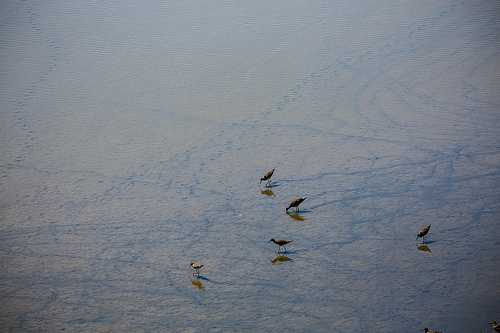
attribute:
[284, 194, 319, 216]
bird — walking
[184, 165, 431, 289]
birds flock — looking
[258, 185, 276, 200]
shadow — black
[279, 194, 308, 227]
bird — standing, pecking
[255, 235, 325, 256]
bird — brown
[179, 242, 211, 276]
bird — brown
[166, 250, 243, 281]
bird — walking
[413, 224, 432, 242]
bird — brown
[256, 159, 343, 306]
bird — brown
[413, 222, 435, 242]
bird — walking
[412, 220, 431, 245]
bird — walking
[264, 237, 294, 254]
bird — walking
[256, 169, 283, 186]
bird — walking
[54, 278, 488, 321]
sand — wet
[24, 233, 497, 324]
sand — wet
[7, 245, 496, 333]
sand — wet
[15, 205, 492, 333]
sand — wet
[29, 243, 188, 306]
lines — dark